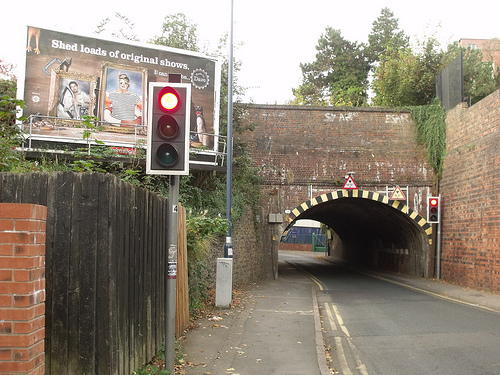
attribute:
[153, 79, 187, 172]
street signal — red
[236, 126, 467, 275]
tunnel — brick, red, brown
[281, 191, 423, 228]
lines — yellow, black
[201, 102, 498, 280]
wall — brick, red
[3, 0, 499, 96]
sky — overcast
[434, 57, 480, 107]
fence — wooden, black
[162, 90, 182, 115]
light — red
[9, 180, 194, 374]
fence — wood, wooden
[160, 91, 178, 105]
traffic signal — red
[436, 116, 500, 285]
brick — red